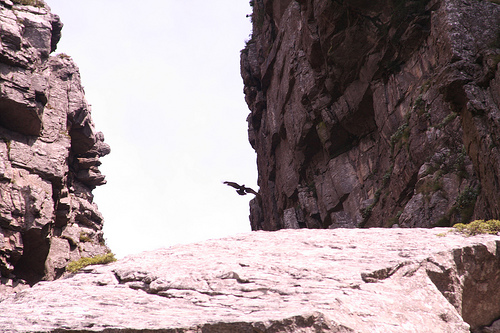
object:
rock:
[0, 229, 500, 330]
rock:
[0, 0, 110, 289]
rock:
[239, 0, 500, 232]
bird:
[220, 180, 259, 198]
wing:
[222, 180, 240, 189]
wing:
[244, 187, 259, 196]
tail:
[235, 190, 247, 196]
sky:
[47, 0, 251, 233]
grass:
[434, 218, 500, 240]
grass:
[63, 251, 117, 275]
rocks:
[0, 0, 498, 288]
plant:
[13, 0, 45, 8]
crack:
[354, 11, 383, 31]